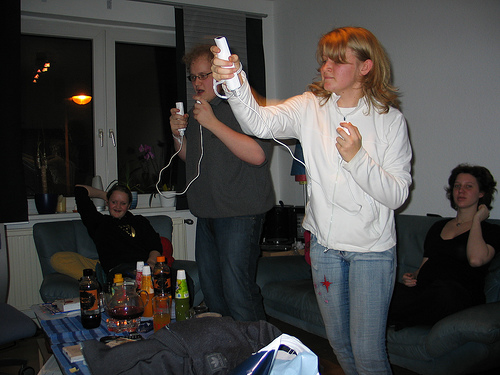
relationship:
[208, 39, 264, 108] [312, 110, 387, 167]
remotes in hand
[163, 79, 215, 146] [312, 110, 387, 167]
remotes in hand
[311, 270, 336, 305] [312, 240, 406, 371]
designs on jeans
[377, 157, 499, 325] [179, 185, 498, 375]
woman on couch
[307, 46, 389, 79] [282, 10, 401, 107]
glasses on face